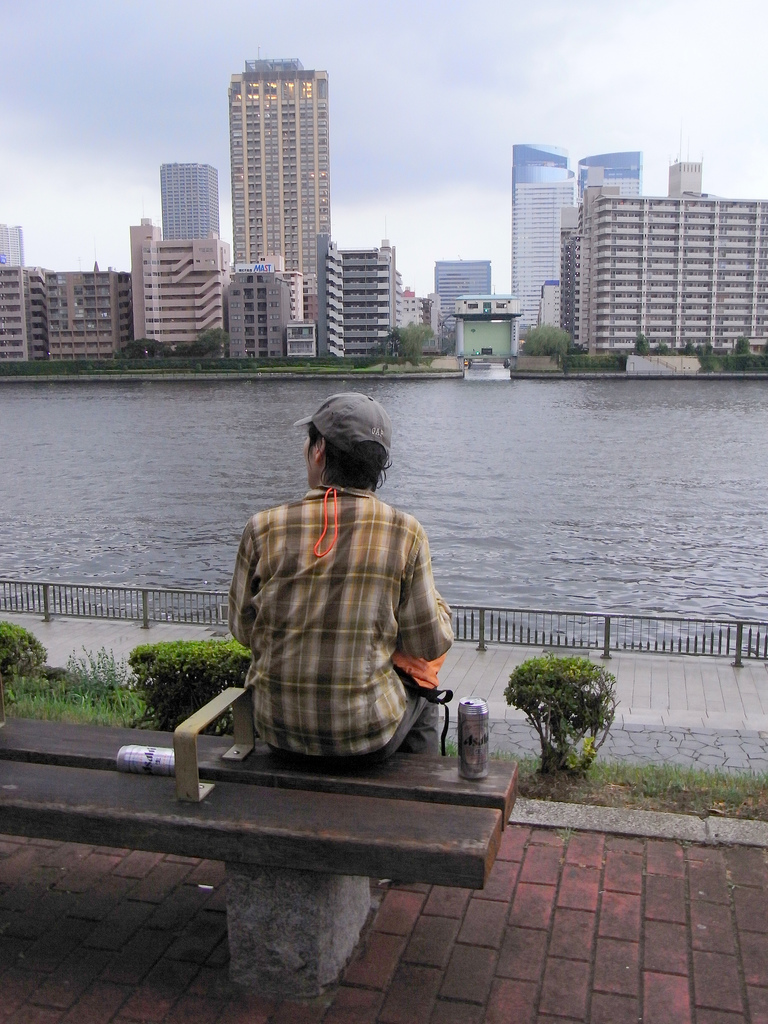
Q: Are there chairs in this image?
A: No, there are no chairs.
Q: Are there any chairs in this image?
A: No, there are no chairs.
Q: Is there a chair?
A: No, there are no chairs.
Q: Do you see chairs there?
A: No, there are no chairs.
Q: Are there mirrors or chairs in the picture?
A: No, there are no chairs or mirrors.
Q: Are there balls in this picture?
A: No, there are no balls.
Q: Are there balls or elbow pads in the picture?
A: No, there are no balls or elbow pads.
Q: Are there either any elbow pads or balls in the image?
A: No, there are no balls or elbow pads.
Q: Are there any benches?
A: Yes, there is a bench.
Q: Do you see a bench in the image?
A: Yes, there is a bench.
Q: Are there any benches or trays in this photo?
A: Yes, there is a bench.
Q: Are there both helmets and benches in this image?
A: No, there is a bench but no helmets.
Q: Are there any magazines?
A: No, there are no magazines.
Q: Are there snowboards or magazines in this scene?
A: No, there are no magazines or snowboards.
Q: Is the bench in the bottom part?
A: Yes, the bench is in the bottom of the image.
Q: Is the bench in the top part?
A: No, the bench is in the bottom of the image.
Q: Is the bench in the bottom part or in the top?
A: The bench is in the bottom of the image.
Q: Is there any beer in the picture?
A: Yes, there is beer.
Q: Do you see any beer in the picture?
A: Yes, there is beer.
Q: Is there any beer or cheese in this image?
A: Yes, there is beer.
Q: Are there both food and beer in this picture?
A: No, there is beer but no food.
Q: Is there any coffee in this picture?
A: No, there is no coffee.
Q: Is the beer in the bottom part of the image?
A: Yes, the beer is in the bottom of the image.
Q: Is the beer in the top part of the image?
A: No, the beer is in the bottom of the image.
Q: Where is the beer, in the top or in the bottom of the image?
A: The beer is in the bottom of the image.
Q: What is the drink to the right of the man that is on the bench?
A: The drink is beer.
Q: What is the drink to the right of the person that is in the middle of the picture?
A: The drink is beer.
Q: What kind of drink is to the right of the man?
A: The drink is beer.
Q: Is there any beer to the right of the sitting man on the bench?
A: Yes, there is beer to the right of the man.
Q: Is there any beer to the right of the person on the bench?
A: Yes, there is beer to the right of the man.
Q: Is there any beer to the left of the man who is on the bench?
A: No, the beer is to the right of the man.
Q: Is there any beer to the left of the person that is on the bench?
A: No, the beer is to the right of the man.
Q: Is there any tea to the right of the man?
A: No, there is beer to the right of the man.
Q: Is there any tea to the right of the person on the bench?
A: No, there is beer to the right of the man.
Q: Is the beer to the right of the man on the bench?
A: Yes, the beer is to the right of the man.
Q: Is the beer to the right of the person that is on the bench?
A: Yes, the beer is to the right of the man.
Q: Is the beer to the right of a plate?
A: No, the beer is to the right of the man.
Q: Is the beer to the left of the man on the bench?
A: No, the beer is to the right of the man.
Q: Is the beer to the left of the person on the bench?
A: No, the beer is to the right of the man.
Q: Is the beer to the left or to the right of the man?
A: The beer is to the right of the man.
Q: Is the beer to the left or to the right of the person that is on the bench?
A: The beer is to the right of the man.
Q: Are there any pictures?
A: No, there are no pictures.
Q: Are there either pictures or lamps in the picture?
A: No, there are no pictures or lamps.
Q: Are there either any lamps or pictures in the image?
A: No, there are no pictures or lamps.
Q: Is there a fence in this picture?
A: Yes, there is a fence.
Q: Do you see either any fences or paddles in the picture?
A: Yes, there is a fence.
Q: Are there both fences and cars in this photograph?
A: No, there is a fence but no cars.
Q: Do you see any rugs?
A: No, there are no rugs.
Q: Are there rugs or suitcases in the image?
A: No, there are no rugs or suitcases.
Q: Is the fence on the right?
A: Yes, the fence is on the right of the image.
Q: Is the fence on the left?
A: No, the fence is on the right of the image.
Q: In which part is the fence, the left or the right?
A: The fence is on the right of the image.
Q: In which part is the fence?
A: The fence is on the right of the image.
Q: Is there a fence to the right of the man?
A: Yes, there is a fence to the right of the man.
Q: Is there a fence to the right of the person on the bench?
A: Yes, there is a fence to the right of the man.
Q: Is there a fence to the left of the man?
A: No, the fence is to the right of the man.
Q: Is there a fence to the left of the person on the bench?
A: No, the fence is to the right of the man.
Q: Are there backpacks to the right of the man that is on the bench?
A: No, there is a fence to the right of the man.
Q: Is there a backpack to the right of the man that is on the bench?
A: No, there is a fence to the right of the man.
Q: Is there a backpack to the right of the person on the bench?
A: No, there is a fence to the right of the man.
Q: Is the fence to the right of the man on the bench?
A: Yes, the fence is to the right of the man.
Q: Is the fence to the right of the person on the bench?
A: Yes, the fence is to the right of the man.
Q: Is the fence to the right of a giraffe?
A: No, the fence is to the right of the man.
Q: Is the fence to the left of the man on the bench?
A: No, the fence is to the right of the man.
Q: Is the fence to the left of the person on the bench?
A: No, the fence is to the right of the man.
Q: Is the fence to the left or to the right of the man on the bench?
A: The fence is to the right of the man.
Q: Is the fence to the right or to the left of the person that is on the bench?
A: The fence is to the right of the man.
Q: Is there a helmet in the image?
A: No, there are no helmets.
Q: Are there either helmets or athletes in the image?
A: No, there are no helmets or athletes.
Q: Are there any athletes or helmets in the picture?
A: No, there are no helmets or athletes.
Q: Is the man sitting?
A: Yes, the man is sitting.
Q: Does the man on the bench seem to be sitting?
A: Yes, the man is sitting.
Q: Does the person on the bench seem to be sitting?
A: Yes, the man is sitting.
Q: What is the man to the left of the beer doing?
A: The man is sitting.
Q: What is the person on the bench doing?
A: The man is sitting.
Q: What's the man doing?
A: The man is sitting.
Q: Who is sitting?
A: The man is sitting.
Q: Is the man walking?
A: No, the man is sitting.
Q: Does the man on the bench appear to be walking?
A: No, the man is sitting.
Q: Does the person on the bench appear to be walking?
A: No, the man is sitting.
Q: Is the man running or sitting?
A: The man is sitting.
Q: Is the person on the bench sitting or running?
A: The man is sitting.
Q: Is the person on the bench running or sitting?
A: The man is sitting.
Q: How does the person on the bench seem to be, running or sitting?
A: The man is sitting.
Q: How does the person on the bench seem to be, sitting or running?
A: The man is sitting.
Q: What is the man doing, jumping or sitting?
A: The man is sitting.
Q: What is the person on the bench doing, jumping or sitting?
A: The man is sitting.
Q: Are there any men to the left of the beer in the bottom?
A: Yes, there is a man to the left of the beer.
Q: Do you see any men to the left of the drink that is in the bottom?
A: Yes, there is a man to the left of the beer.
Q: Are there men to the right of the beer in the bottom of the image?
A: No, the man is to the left of the beer.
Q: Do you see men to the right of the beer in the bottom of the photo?
A: No, the man is to the left of the beer.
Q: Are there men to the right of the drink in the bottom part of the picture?
A: No, the man is to the left of the beer.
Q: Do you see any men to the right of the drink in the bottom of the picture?
A: No, the man is to the left of the beer.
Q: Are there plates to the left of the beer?
A: No, there is a man to the left of the beer.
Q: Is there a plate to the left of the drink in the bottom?
A: No, there is a man to the left of the beer.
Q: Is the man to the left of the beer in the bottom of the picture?
A: Yes, the man is to the left of the beer.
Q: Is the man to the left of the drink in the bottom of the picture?
A: Yes, the man is to the left of the beer.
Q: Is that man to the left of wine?
A: No, the man is to the left of the beer.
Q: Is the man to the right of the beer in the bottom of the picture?
A: No, the man is to the left of the beer.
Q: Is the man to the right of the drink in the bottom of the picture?
A: No, the man is to the left of the beer.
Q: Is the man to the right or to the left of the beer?
A: The man is to the left of the beer.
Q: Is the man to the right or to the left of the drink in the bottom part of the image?
A: The man is to the left of the beer.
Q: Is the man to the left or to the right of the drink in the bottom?
A: The man is to the left of the beer.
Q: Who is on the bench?
A: The man is on the bench.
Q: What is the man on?
A: The man is on the bench.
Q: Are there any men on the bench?
A: Yes, there is a man on the bench.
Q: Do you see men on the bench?
A: Yes, there is a man on the bench.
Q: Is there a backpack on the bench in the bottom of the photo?
A: No, there is a man on the bench.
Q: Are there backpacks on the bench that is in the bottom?
A: No, there is a man on the bench.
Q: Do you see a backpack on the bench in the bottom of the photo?
A: No, there is a man on the bench.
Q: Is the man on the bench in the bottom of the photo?
A: Yes, the man is on the bench.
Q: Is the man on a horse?
A: No, the man is on the bench.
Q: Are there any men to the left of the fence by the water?
A: Yes, there is a man to the left of the fence.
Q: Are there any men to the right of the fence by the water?
A: No, the man is to the left of the fence.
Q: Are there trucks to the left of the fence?
A: No, there is a man to the left of the fence.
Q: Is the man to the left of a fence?
A: Yes, the man is to the left of a fence.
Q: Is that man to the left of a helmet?
A: No, the man is to the left of a fence.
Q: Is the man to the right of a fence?
A: No, the man is to the left of a fence.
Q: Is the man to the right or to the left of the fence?
A: The man is to the left of the fence.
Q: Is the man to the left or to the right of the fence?
A: The man is to the left of the fence.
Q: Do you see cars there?
A: No, there are no cars.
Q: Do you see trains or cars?
A: No, there are no cars or trains.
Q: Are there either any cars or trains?
A: No, there are no cars or trains.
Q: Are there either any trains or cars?
A: No, there are no cars or trains.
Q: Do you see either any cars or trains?
A: No, there are no cars or trains.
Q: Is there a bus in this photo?
A: No, there are no buses.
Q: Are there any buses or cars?
A: No, there are no buses or cars.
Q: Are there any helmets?
A: No, there are no helmets.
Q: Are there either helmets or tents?
A: No, there are no helmets or tents.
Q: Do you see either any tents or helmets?
A: No, there are no helmets or tents.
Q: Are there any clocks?
A: No, there are no clocks.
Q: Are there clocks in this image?
A: No, there are no clocks.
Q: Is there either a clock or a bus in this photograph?
A: No, there are no clocks or buses.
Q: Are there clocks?
A: No, there are no clocks.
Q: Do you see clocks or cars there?
A: No, there are no clocks or cars.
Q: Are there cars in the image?
A: No, there are no cars.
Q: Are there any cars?
A: No, there are no cars.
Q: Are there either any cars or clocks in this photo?
A: No, there are no cars or clocks.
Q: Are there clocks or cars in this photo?
A: No, there are no cars or clocks.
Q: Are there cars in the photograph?
A: No, there are no cars.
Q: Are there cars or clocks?
A: No, there are no cars or clocks.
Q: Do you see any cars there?
A: No, there are no cars.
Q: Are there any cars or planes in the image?
A: No, there are no cars or planes.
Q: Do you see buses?
A: No, there are no buses.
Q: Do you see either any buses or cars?
A: No, there are no buses or cars.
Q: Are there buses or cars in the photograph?
A: No, there are no buses or cars.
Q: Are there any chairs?
A: No, there are no chairs.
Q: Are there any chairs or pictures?
A: No, there are no chairs or pictures.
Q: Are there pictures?
A: No, there are no pictures.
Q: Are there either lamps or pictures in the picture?
A: No, there are no pictures or lamps.